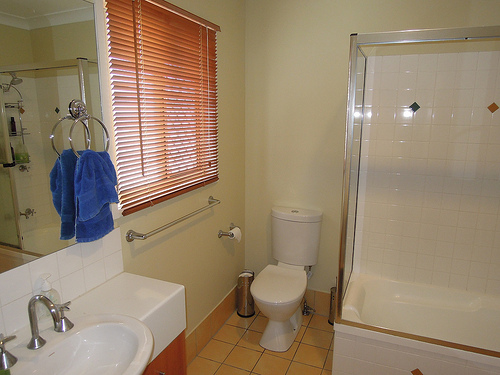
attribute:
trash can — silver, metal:
[236, 267, 256, 318]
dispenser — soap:
[40, 271, 60, 331]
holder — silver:
[217, 222, 238, 242]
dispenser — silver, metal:
[219, 220, 245, 241]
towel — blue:
[71, 155, 113, 218]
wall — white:
[241, 3, 496, 298]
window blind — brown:
[106, 0, 221, 215]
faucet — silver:
[8, 279, 88, 351]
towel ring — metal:
[66, 112, 112, 159]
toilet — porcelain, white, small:
[247, 204, 325, 354]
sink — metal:
[6, 295, 150, 373]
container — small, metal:
[219, 266, 273, 320]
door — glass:
[338, 28, 497, 362]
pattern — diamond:
[213, 324, 313, 371]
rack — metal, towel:
[63, 103, 114, 158]